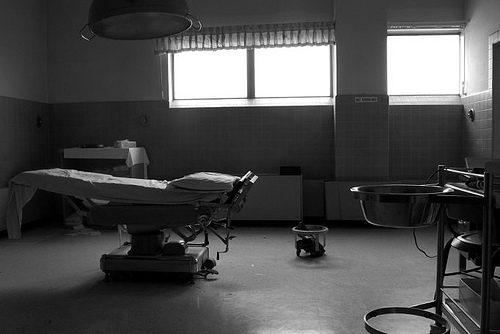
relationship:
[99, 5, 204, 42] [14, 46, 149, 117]
circle in room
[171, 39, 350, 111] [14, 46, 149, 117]
windows are in room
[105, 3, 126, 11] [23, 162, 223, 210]
light above bed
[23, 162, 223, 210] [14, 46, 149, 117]
bed in room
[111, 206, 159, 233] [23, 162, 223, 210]
bottom of bed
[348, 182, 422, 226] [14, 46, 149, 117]
sink in room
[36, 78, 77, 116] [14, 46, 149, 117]
side of room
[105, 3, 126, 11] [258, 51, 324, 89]
light shines through window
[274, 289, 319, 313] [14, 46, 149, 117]
ground of room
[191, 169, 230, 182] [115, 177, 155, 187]
pillow on top of table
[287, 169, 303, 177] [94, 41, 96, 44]
vent and furnace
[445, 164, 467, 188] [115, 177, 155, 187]
instruments are on table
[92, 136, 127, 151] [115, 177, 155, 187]
bowl on table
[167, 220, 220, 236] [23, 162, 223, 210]
controls for bed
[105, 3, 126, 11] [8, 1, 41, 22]
light on ceiling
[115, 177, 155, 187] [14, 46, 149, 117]
table in room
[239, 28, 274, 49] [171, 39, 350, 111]
curtains are hanging from windows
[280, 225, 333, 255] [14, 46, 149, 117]
bin in room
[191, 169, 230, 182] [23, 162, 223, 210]
pillow on bed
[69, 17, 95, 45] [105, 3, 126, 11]
handle on light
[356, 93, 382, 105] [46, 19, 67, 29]
sign on wall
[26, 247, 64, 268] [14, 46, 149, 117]
floor of room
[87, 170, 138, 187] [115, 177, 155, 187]
sheet on table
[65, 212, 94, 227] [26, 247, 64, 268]
towels are on floor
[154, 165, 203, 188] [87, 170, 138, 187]
supplies are on top of sheet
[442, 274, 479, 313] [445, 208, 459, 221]
cage in corner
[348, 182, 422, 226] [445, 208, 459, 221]
sink in corner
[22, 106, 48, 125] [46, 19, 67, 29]
ac on wall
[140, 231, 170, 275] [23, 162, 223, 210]
base attached to bed